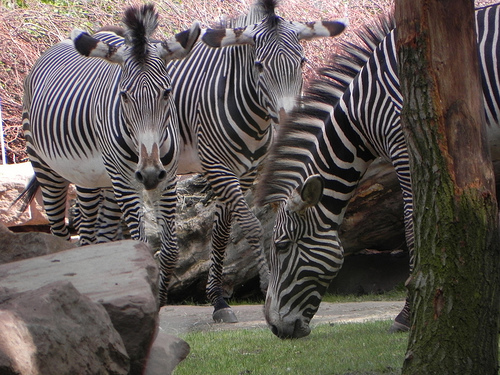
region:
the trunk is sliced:
[383, 7, 470, 182]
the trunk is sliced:
[437, 58, 487, 105]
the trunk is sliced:
[422, 42, 474, 84]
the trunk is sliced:
[370, 101, 477, 215]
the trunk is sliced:
[413, 14, 458, 146]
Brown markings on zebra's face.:
[134, 136, 174, 168]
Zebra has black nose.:
[123, 165, 202, 204]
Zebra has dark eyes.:
[106, 82, 200, 119]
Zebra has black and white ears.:
[70, 29, 250, 73]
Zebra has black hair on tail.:
[10, 176, 52, 207]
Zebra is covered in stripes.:
[14, 80, 163, 202]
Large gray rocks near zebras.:
[58, 237, 153, 368]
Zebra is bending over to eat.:
[246, 289, 316, 361]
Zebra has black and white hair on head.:
[251, 117, 305, 169]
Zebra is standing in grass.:
[321, 297, 441, 347]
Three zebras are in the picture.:
[25, 11, 405, 343]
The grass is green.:
[217, 342, 375, 373]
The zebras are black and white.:
[22, 13, 399, 342]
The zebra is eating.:
[219, 75, 387, 347]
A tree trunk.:
[376, 1, 498, 373]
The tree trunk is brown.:
[380, 0, 499, 373]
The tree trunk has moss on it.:
[390, 167, 498, 373]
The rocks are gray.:
[0, 216, 195, 371]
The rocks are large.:
[0, 214, 195, 374]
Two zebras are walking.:
[12, 11, 339, 331]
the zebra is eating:
[232, 161, 370, 292]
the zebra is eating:
[246, 158, 283, 303]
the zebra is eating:
[236, 192, 358, 366]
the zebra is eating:
[233, 140, 308, 297]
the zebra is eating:
[190, 65, 360, 360]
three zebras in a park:
[22, 6, 497, 337]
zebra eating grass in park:
[264, 193, 411, 373]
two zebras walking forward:
[26, 4, 313, 183]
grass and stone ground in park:
[348, 261, 380, 368]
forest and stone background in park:
[4, 7, 28, 229]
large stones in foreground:
[2, 238, 167, 370]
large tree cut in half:
[414, 4, 495, 371]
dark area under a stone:
[351, 191, 408, 301]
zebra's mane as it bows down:
[259, 124, 362, 214]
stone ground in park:
[327, 301, 392, 321]